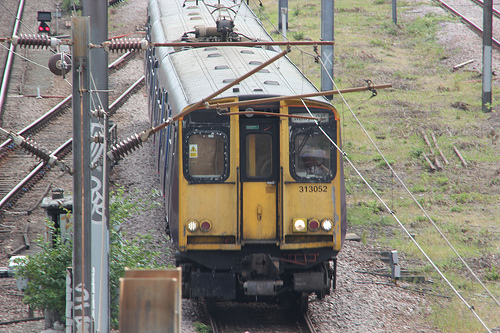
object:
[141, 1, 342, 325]
train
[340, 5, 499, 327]
field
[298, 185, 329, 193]
number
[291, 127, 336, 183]
window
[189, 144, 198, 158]
tag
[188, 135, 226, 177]
window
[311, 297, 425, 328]
gravel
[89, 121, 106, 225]
writing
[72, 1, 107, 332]
pole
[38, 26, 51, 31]
lights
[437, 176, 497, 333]
grass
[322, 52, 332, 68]
x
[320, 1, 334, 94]
pole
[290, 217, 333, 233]
lights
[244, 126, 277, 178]
windows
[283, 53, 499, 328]
wires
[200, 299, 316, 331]
tracks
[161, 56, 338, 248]
caboose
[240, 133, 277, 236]
door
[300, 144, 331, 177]
conductor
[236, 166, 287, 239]
handles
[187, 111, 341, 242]
train rear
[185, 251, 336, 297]
bottom